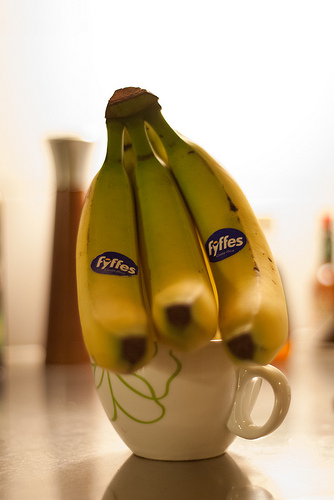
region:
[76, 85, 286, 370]
Three ripe yellow bananas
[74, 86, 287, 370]
Bunch of ripe bananas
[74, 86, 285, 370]
Three bananas with stickers on them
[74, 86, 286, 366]
Front view of three bananas attached to each other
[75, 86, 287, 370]
Yellow bananas with blue stickers on them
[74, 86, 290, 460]
Bananas sitting on top of a cup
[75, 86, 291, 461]
Three bananas and a mug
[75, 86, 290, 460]
Bananas sitting on a cup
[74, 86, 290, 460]
Bananas balanced on a mug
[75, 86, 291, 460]
Yellow bananas on a white and green cup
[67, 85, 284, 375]
Yellow bananas on a cup.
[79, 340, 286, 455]
Cup is white with green flower design.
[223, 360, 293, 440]
Cup handle is white.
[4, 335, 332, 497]
Cup is on a table.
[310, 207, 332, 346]
A bottle of Tabasco sauce in the background.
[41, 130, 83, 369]
A bottle of ketchup in the background.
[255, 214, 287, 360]
A bottle of maple syrup behind the bananas.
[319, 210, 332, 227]
The lid of the Tabasco sauce is red.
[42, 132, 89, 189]
The lid of the ketchup bottle is white.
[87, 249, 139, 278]
Banana with blue label "fyffes".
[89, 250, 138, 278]
Oval blue sticker on a banana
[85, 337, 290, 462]
Small white tea cup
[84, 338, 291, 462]
White mug with green swirls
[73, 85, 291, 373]
Bunch of unripe bananas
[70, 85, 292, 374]
Three almost ripe yellow bananas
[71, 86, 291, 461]
Bunch of bananas on a white mug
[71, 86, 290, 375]
Bunch of three bananas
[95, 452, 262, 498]
Reflection of a cup on the table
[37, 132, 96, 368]
Brown and white wood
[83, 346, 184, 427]
Lime green swirls on a cup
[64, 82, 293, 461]
bananas on top of a tea cup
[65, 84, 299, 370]
a bundle of yellow bananas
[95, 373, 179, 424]
part of a green floral design on a tea cup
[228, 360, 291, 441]
handle of a tea cup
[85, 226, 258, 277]
stickers on bananas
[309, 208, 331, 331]
bottle of tobasco sauce in the background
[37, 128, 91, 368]
bottle of seasoning in the background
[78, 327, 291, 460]
a cream tea cup with bananas on top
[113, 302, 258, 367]
ends of three bananas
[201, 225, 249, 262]
fyffes sticker on banana